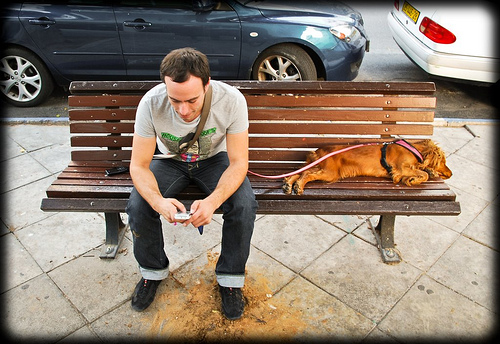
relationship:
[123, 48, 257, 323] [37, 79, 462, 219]
man on bench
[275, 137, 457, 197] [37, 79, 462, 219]
dog on bench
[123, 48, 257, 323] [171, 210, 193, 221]
man on cellphone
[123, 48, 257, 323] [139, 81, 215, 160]
man wearing bag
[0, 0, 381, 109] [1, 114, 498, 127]
car on curb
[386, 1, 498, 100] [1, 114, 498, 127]
car on curb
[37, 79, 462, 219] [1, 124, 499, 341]
bench on sidewalk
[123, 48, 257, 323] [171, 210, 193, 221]
man holding cellphone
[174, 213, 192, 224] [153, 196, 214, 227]
object in hands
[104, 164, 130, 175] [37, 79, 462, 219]
phone on bench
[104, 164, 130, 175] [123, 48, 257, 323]
phone beside man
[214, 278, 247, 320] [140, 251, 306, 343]
foot in dirt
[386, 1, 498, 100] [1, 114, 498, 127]
vehicle near curb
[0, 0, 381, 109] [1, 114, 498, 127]
vehicle near curb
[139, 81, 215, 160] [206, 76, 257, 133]
strap around shoulder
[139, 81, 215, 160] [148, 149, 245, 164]
strap around waist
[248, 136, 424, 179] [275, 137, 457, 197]
leash on dog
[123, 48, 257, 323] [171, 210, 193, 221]
man looking at cellphone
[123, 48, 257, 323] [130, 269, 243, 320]
man wearing shoes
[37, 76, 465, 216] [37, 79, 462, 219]
slats on bench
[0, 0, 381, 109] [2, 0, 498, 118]
car in traffic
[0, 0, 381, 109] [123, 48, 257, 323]
car behind man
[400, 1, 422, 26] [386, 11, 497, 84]
tag on bumper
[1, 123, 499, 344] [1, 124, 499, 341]
tile on sidewalk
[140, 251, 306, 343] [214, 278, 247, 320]
dirt under foot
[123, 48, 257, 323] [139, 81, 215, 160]
man has strap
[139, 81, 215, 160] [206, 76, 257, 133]
strap on shoulder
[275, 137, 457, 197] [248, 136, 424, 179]
dog on leash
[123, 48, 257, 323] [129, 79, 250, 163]
man wearing tee